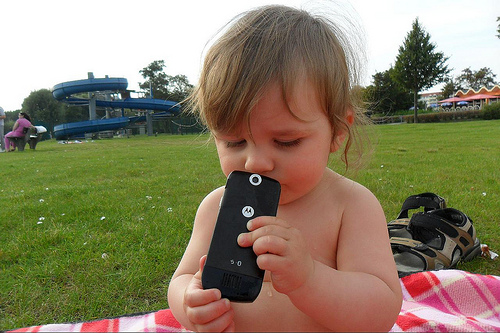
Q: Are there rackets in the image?
A: No, there are no rackets.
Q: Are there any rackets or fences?
A: No, there are no rackets or fences.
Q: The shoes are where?
A: The shoes are on the ground.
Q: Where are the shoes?
A: The shoes are on the ground.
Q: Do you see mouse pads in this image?
A: No, there are no mouse pads.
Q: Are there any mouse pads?
A: No, there are no mouse pads.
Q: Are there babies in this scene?
A: Yes, there is a baby.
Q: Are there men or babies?
A: Yes, there is a baby.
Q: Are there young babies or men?
A: Yes, there is a young baby.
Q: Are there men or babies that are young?
A: Yes, the baby is young.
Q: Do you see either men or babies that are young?
A: Yes, the baby is young.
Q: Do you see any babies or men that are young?
A: Yes, the baby is young.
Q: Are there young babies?
A: Yes, there is a young baby.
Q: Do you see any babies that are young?
A: Yes, there is a baby that is young.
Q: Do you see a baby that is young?
A: Yes, there is a baby that is young.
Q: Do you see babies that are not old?
A: Yes, there is an young baby.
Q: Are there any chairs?
A: No, there are no chairs.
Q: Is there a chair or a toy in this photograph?
A: No, there are no chairs or toys.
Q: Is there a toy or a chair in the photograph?
A: No, there are no chairs or toys.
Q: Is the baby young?
A: Yes, the baby is young.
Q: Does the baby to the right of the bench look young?
A: Yes, the baby is young.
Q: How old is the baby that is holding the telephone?
A: The baby is young.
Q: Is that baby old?
A: No, the baby is young.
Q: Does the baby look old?
A: No, the baby is young.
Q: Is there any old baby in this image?
A: No, there is a baby but he is young.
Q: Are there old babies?
A: No, there is a baby but he is young.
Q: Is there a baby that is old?
A: No, there is a baby but he is young.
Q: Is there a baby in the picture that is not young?
A: No, there is a baby but he is young.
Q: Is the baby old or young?
A: The baby is young.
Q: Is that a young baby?
A: Yes, that is a young baby.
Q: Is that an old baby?
A: No, that is a young baby.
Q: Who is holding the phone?
A: The baby is holding the telephone.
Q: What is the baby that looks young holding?
A: The baby is holding the phone.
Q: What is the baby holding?
A: The baby is holding the phone.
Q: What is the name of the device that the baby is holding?
A: The device is a phone.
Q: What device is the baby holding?
A: The baby is holding the telephone.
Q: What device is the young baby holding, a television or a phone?
A: The baby is holding a phone.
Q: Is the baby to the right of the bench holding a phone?
A: Yes, the baby is holding a phone.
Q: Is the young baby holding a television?
A: No, the baby is holding a phone.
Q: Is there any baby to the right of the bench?
A: Yes, there is a baby to the right of the bench.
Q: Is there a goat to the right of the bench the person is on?
A: No, there is a baby to the right of the bench.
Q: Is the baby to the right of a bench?
A: Yes, the baby is to the right of a bench.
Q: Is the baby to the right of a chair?
A: No, the baby is to the right of a bench.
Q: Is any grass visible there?
A: Yes, there is grass.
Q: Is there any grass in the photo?
A: Yes, there is grass.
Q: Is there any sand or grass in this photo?
A: Yes, there is grass.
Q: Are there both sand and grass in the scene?
A: No, there is grass but no sand.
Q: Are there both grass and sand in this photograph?
A: No, there is grass but no sand.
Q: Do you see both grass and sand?
A: No, there is grass but no sand.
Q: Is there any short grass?
A: Yes, there is short grass.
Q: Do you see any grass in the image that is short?
A: Yes, there is short grass.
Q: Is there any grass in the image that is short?
A: Yes, there is grass that is short.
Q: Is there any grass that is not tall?
A: Yes, there is short grass.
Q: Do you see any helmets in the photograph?
A: No, there are no helmets.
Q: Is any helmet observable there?
A: No, there are no helmets.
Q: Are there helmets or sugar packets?
A: No, there are no helmets or sugar packets.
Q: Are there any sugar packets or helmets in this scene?
A: No, there are no helmets or sugar packets.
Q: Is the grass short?
A: Yes, the grass is short.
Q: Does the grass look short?
A: Yes, the grass is short.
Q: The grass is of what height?
A: The grass is short.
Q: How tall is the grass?
A: The grass is short.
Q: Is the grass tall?
A: No, the grass is short.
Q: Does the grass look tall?
A: No, the grass is short.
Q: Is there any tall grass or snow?
A: No, there is grass but it is short.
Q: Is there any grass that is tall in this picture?
A: No, there is grass but it is short.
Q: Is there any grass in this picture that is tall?
A: No, there is grass but it is short.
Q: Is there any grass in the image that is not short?
A: No, there is grass but it is short.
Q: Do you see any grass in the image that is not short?
A: No, there is grass but it is short.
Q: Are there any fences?
A: No, there are no fences.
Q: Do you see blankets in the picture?
A: Yes, there is a blanket.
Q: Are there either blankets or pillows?
A: Yes, there is a blanket.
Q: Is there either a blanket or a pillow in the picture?
A: Yes, there is a blanket.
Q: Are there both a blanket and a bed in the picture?
A: No, there is a blanket but no beds.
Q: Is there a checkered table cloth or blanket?
A: Yes, there is a checkered blanket.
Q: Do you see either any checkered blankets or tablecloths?
A: Yes, there is a checkered blanket.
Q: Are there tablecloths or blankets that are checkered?
A: Yes, the blanket is checkered.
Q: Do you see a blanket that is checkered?
A: Yes, there is a checkered blanket.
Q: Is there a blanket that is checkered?
A: Yes, there is a blanket that is checkered.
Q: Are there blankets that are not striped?
A: Yes, there is a checkered blanket.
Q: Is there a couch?
A: No, there are no couches.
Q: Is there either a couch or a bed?
A: No, there are no couches or beds.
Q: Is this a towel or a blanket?
A: This is a blanket.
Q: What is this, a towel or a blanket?
A: This is a blanket.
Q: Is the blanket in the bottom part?
A: Yes, the blanket is in the bottom of the image.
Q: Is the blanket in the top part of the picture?
A: No, the blanket is in the bottom of the image.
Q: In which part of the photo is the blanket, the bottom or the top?
A: The blanket is in the bottom of the image.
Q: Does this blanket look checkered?
A: Yes, the blanket is checkered.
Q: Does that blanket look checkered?
A: Yes, the blanket is checkered.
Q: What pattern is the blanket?
A: The blanket is checkered.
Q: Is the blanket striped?
A: No, the blanket is checkered.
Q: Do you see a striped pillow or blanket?
A: No, there is a blanket but it is checkered.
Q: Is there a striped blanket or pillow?
A: No, there is a blanket but it is checkered.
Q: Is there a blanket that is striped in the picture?
A: No, there is a blanket but it is checkered.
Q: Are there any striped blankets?
A: No, there is a blanket but it is checkered.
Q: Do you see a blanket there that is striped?
A: No, there is a blanket but it is checkered.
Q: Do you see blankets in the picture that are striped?
A: No, there is a blanket but it is checkered.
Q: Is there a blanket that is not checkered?
A: No, there is a blanket but it is checkered.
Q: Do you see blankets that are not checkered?
A: No, there is a blanket but it is checkered.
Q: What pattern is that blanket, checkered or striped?
A: The blanket is checkered.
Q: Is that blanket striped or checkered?
A: The blanket is checkered.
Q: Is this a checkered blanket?
A: Yes, this is a checkered blanket.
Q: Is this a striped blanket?
A: No, this is a checkered blanket.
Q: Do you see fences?
A: No, there are no fences.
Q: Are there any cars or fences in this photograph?
A: No, there are no fences or cars.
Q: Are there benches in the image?
A: Yes, there is a bench.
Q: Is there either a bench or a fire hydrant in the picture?
A: Yes, there is a bench.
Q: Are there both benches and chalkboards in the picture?
A: No, there is a bench but no chalkboards.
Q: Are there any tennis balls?
A: No, there are no tennis balls.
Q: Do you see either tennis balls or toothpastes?
A: No, there are no tennis balls or toothpastes.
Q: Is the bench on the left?
A: Yes, the bench is on the left of the image.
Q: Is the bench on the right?
A: No, the bench is on the left of the image.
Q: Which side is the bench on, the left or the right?
A: The bench is on the left of the image.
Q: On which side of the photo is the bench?
A: The bench is on the left of the image.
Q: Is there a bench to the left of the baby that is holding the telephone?
A: Yes, there is a bench to the left of the baby.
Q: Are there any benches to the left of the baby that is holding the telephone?
A: Yes, there is a bench to the left of the baby.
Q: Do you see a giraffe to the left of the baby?
A: No, there is a bench to the left of the baby.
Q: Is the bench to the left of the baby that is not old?
A: Yes, the bench is to the left of the baby.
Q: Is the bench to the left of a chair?
A: No, the bench is to the left of the baby.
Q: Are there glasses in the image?
A: No, there are no glasses.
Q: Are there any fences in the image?
A: No, there are no fences.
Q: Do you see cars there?
A: No, there are no cars.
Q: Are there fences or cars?
A: No, there are no cars or fences.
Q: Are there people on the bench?
A: Yes, there is a person on the bench.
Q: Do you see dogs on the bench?
A: No, there is a person on the bench.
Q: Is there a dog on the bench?
A: No, there is a person on the bench.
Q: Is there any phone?
A: Yes, there is a phone.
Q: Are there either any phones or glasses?
A: Yes, there is a phone.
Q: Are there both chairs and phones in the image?
A: No, there is a phone but no chairs.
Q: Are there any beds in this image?
A: No, there are no beds.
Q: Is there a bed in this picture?
A: No, there are no beds.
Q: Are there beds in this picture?
A: No, there are no beds.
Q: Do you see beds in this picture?
A: No, there are no beds.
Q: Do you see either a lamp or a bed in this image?
A: No, there are no beds or lamps.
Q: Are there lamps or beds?
A: No, there are no beds or lamps.